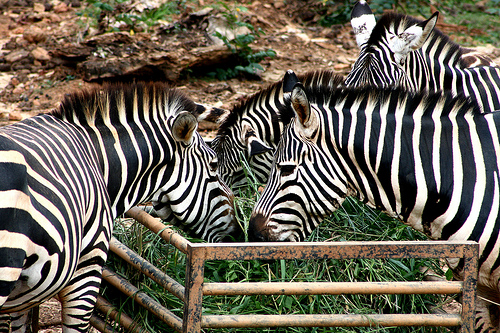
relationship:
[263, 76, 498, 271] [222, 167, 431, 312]
zebra eat plants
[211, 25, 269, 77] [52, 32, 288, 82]
plants growing under brown rock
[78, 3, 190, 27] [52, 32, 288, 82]
plants growing under brown rock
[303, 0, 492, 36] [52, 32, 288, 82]
plants growing under brown rock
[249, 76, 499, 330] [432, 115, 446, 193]
zebra has skin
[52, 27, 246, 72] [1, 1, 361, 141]
brown rock on ground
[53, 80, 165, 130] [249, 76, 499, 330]
mane of zebra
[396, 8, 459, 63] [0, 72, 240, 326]
mane of zebra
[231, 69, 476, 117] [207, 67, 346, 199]
mane of zebra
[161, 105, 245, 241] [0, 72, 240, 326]
face of zebra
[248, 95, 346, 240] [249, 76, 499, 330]
face of zebra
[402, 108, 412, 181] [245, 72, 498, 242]
skin of zebra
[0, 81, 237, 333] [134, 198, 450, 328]
animal eating grass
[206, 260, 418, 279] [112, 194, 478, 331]
grass in trough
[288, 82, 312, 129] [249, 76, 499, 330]
ear of zebra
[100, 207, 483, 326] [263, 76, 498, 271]
fence before zebra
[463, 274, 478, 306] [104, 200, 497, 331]
marks in gate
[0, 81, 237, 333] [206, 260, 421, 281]
animal standing in grass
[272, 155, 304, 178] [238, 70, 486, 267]
eye on zebra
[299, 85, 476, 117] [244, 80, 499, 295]
mane on zebra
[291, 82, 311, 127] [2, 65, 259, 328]
ear on zebra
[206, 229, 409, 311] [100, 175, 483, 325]
grass in fence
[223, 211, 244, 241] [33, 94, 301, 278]
nose of animal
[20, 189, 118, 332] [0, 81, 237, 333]
stomach of animal